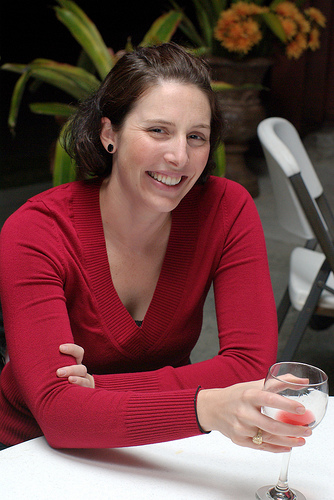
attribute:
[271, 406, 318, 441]
wine — red, small amount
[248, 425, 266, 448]
ring — gold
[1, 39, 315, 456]
woman — smiling, makeup free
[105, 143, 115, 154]
earring — round, black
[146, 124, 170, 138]
eye — dark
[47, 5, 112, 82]
leaf — long, green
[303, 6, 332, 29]
flower — orange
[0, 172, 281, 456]
sweater — red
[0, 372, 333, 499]
table — white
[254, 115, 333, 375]
chair — white, folding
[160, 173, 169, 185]
tooth — white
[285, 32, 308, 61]
flower — yellow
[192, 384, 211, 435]
bracelet — small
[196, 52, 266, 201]
pot — large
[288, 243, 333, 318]
seating — white